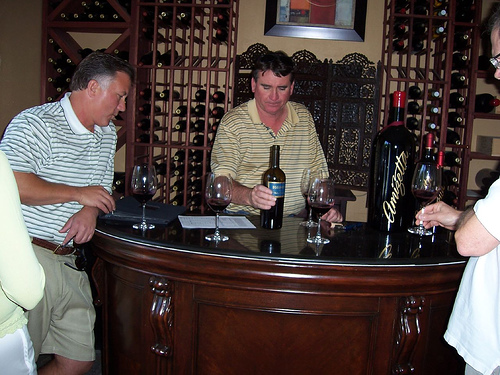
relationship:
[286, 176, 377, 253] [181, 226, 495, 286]
glasses on bar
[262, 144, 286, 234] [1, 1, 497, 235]
wine on wall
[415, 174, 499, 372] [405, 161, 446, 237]
man holding glasses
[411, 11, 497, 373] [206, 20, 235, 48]
man holding wine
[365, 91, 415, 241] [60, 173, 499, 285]
bottle on counter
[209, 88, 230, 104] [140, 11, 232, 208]
wine bottle on rack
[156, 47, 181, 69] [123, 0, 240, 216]
bottle on rack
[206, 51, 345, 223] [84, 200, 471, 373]
man behind bar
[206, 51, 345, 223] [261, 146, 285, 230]
man holding wine bottle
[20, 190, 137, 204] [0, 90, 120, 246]
man wearing shirt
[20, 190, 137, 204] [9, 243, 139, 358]
man wearing khaki shorts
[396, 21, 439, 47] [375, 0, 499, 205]
bottle on rack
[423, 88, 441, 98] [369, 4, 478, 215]
bottle on rack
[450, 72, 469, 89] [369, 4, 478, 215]
bottle on rack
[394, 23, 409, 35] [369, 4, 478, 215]
bottle on rack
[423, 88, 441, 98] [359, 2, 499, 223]
bottle on rack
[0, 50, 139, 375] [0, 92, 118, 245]
man wearing shirt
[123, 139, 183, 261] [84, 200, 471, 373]
glass on bar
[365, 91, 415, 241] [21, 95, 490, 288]
bottle on bar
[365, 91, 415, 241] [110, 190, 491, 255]
bottle on counter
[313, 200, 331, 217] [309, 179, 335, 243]
wine in glass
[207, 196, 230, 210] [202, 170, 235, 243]
wine in glass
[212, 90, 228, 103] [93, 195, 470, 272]
wine bottle on counter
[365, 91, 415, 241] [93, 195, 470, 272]
bottle on counter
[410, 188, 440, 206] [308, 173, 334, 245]
wine in glass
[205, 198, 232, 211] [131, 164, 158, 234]
wine in glass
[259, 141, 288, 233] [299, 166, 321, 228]
wine in glass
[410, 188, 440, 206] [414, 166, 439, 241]
wine in glass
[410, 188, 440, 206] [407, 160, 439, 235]
wine in glass